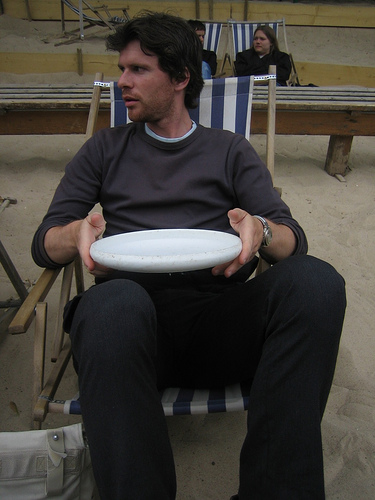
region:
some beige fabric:
[0, 424, 94, 499]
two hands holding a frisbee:
[64, 206, 289, 279]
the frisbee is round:
[90, 221, 248, 272]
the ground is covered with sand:
[4, 128, 372, 496]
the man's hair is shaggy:
[99, 7, 208, 112]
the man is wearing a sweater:
[30, 118, 313, 281]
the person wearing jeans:
[193, 60, 216, 80]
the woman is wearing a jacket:
[225, 43, 297, 87]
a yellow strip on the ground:
[2, 44, 371, 92]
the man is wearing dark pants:
[43, 247, 333, 497]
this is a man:
[86, 33, 308, 320]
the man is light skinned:
[139, 77, 155, 103]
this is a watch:
[261, 211, 273, 247]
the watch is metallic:
[259, 212, 266, 229]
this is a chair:
[12, 296, 57, 401]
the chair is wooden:
[19, 303, 46, 341]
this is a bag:
[9, 431, 72, 491]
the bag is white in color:
[7, 441, 29, 479]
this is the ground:
[191, 429, 219, 478]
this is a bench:
[282, 76, 354, 132]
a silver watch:
[252, 215, 271, 250]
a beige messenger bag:
[0, 420, 95, 498]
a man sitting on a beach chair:
[31, 10, 347, 498]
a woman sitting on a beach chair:
[232, 24, 293, 87]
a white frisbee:
[90, 228, 242, 271]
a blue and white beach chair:
[8, 65, 278, 431]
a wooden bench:
[0, 84, 374, 179]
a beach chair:
[55, 0, 131, 48]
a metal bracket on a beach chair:
[248, 74, 276, 80]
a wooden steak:
[75, 47, 82, 77]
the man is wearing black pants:
[54, 242, 354, 497]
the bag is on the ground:
[0, 418, 91, 498]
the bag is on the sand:
[0, 418, 93, 499]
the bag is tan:
[0, 413, 90, 498]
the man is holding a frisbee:
[87, 226, 247, 277]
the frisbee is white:
[84, 214, 251, 286]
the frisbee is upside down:
[88, 225, 247, 287]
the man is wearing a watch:
[245, 206, 277, 255]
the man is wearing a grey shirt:
[31, 112, 319, 288]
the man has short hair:
[103, 8, 210, 113]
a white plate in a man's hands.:
[84, 220, 259, 276]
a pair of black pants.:
[65, 242, 354, 498]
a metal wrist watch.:
[251, 214, 278, 271]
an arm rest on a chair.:
[11, 220, 111, 423]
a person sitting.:
[218, 18, 309, 102]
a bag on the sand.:
[0, 412, 99, 497]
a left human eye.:
[120, 55, 154, 82]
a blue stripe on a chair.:
[228, 70, 268, 148]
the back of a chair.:
[237, 55, 288, 177]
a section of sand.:
[345, 407, 363, 445]